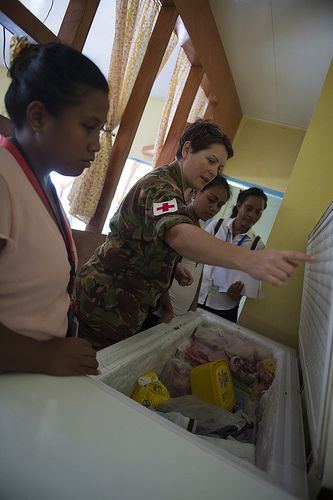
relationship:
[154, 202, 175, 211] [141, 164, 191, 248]
cross on sleeve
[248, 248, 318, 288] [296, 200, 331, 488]
hand on door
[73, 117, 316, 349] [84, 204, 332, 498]
woman pointing at freezer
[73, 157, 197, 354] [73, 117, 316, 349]
uniform on woman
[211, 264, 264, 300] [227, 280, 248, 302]
papers in hand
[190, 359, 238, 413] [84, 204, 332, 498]
container in freezer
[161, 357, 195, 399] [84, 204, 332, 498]
meat in freezer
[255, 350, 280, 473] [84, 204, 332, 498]
frost on side of freezer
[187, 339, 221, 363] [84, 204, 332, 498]
meat in freezer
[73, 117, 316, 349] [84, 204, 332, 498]
woman looking into freezer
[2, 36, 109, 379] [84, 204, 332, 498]
woman looking into freezer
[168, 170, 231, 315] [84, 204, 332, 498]
woman looking into freezer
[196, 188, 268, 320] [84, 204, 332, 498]
woman looking into freezer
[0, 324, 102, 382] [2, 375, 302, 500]
arm resting on freezer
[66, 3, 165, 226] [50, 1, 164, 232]
curtain hanging over thew window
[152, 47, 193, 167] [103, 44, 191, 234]
curtain hanging over thew window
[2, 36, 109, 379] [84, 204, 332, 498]
woman looking at freezer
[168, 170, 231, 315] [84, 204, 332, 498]
woman looking at freezer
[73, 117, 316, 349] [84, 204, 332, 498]
woman looking at freezer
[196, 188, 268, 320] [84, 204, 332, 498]
woman looking at freezer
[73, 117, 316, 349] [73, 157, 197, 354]
woman in uniform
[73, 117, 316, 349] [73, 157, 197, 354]
woman wearing uniform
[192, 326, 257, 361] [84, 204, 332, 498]
food in freezer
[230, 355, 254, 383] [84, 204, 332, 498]
food in freezer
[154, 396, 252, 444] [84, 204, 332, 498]
food in freezer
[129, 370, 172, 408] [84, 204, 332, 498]
bag in freezer